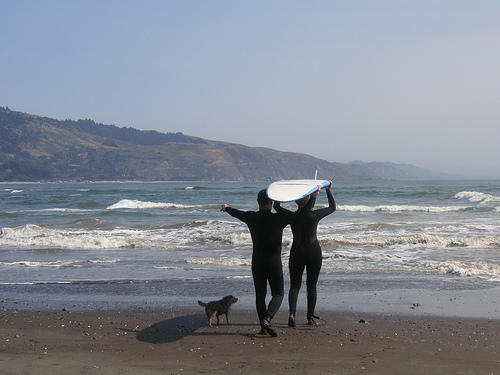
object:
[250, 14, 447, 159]
clouds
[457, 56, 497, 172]
clouds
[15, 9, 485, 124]
sky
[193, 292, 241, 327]
dog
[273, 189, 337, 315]
wet suit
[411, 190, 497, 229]
wave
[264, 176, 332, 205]
surfboard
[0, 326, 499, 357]
ground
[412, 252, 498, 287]
wave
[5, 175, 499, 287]
water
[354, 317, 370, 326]
brown rock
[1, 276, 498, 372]
beach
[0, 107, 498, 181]
hills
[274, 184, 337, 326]
person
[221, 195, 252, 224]
arm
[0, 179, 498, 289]
ocean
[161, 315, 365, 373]
sand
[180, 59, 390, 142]
clouds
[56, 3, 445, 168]
sky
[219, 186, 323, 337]
people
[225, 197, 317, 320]
wetsuits